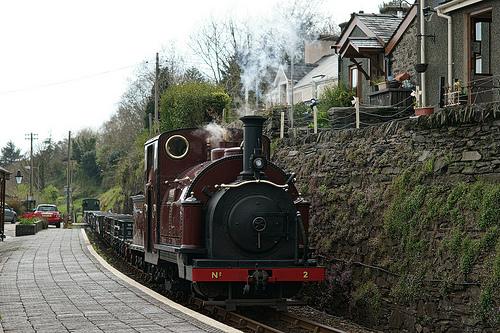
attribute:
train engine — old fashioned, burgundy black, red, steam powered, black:
[129, 115, 326, 311]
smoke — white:
[190, 0, 324, 149]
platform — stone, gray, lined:
[0, 228, 246, 333]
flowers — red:
[18, 211, 44, 224]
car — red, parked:
[33, 204, 61, 229]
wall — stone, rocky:
[269, 100, 499, 332]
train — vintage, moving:
[82, 116, 325, 312]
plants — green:
[384, 157, 500, 275]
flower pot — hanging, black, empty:
[413, 63, 428, 73]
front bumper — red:
[185, 265, 324, 282]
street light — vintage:
[14, 169, 23, 184]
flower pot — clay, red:
[414, 107, 435, 117]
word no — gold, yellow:
[211, 271, 222, 279]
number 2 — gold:
[303, 271, 309, 280]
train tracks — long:
[96, 232, 348, 333]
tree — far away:
[143, 66, 174, 129]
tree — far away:
[79, 150, 105, 188]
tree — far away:
[1, 139, 24, 168]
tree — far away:
[70, 135, 96, 164]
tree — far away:
[178, 66, 204, 86]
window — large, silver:
[165, 134, 190, 159]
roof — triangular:
[335, 13, 407, 55]